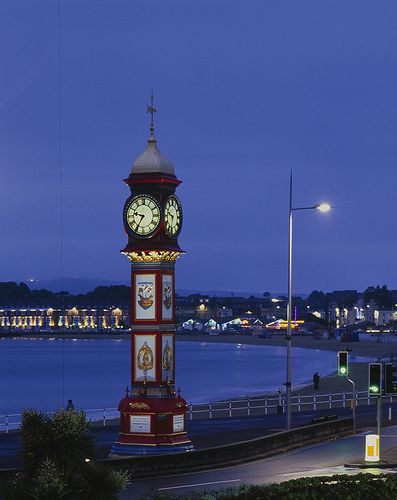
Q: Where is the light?
A: On the pole.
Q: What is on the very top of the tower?
A: Weather vane.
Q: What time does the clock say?
A: 9:35.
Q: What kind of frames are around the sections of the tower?
A: Red lacquer.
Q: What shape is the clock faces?
A: Circle.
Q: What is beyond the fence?
A: A beach.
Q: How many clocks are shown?
A: Two.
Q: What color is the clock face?
A: White.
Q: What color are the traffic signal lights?
A: Green.